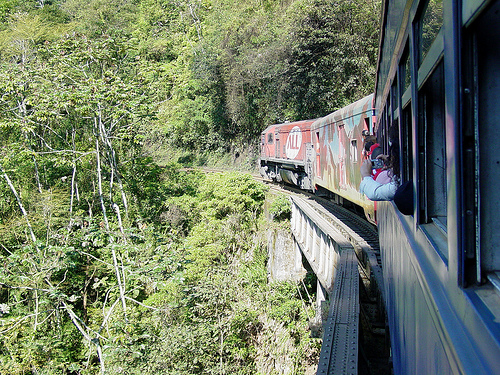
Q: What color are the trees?
A: Green.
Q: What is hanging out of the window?
A: Arm.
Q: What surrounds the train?
A: Trees.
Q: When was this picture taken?
A: Daytime.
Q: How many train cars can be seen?
A: Three.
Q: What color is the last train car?
A: Red.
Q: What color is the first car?
A: Blue.